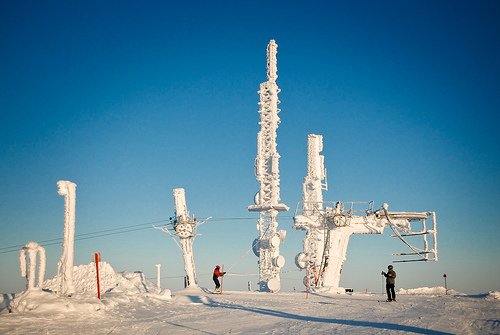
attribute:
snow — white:
[207, 289, 499, 334]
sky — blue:
[0, 5, 495, 290]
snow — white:
[0, 261, 498, 333]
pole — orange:
[93, 252, 104, 304]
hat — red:
[212, 263, 224, 269]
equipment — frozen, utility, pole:
[290, 132, 439, 292]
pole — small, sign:
[439, 271, 448, 293]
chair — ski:
[0, 186, 433, 286]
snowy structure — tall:
[244, 34, 294, 304]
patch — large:
[20, 20, 239, 180]